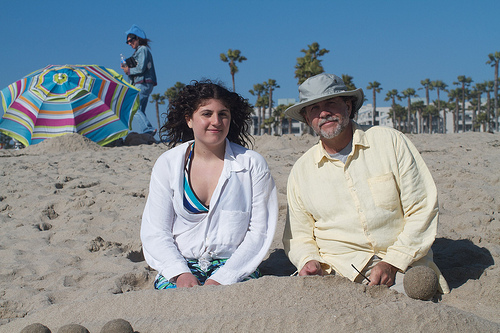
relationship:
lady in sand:
[137, 76, 278, 290] [0, 129, 497, 331]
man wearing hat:
[281, 72, 449, 296] [284, 71, 368, 120]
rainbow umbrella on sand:
[0, 62, 145, 149] [12, 122, 487, 324]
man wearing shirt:
[281, 72, 449, 296] [282, 117, 442, 282]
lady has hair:
[137, 76, 278, 290] [166, 75, 256, 142]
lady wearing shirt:
[137, 76, 278, 290] [282, 117, 442, 282]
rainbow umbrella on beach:
[2, 52, 148, 148] [4, 27, 496, 322]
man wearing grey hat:
[281, 72, 449, 296] [284, 72, 365, 124]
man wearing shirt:
[281, 72, 449, 296] [281, 120, 449, 296]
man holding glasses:
[281, 72, 449, 296] [350, 260, 372, 287]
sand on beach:
[12, 122, 487, 324] [4, 27, 496, 322]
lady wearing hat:
[119, 23, 158, 136] [124, 23, 149, 46]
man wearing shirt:
[281, 72, 449, 296] [285, 124, 440, 289]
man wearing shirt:
[279, 72, 464, 319] [285, 121, 439, 281]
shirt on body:
[285, 121, 439, 281] [288, 129, 465, 286]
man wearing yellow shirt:
[281, 72, 449, 296] [283, 121, 440, 277]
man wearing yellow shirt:
[281, 72, 449, 296] [302, 144, 493, 239]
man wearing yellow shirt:
[281, 72, 449, 296] [281, 122, 453, 294]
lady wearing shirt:
[137, 76, 278, 290] [140, 149, 285, 286]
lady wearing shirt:
[137, 76, 278, 290] [138, 134, 272, 284]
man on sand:
[281, 72, 449, 296] [0, 129, 497, 331]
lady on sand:
[137, 76, 278, 290] [35, 289, 390, 319]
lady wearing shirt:
[137, 76, 278, 290] [140, 137, 277, 286]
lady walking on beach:
[66, 55, 271, 308] [11, 43, 498, 273]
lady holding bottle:
[119, 24, 156, 139] [118, 52, 127, 67]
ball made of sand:
[401, 262, 454, 315] [12, 122, 487, 324]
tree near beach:
[292, 40, 332, 138] [19, 104, 413, 300]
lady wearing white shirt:
[137, 76, 278, 290] [132, 141, 283, 283]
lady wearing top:
[137, 76, 278, 290] [177, 148, 216, 219]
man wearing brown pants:
[281, 72, 449, 296] [388, 257, 453, 298]